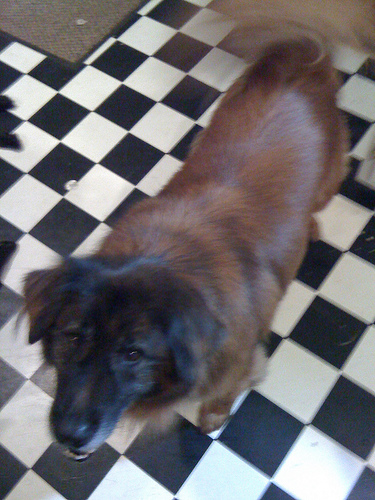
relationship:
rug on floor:
[0, 0, 151, 70] [0, 0, 371, 499]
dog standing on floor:
[24, 0, 375, 470] [0, 0, 371, 499]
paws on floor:
[0, 102, 19, 151] [0, 0, 371, 499]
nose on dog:
[53, 398, 105, 448] [24, 0, 375, 470]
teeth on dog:
[60, 446, 87, 459] [24, 0, 375, 470]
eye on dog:
[123, 344, 146, 366] [24, 0, 375, 470]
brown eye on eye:
[60, 328, 87, 347] [123, 344, 146, 366]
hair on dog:
[41, 44, 358, 466] [145, 67, 338, 310]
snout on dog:
[56, 405, 95, 447] [24, 0, 375, 470]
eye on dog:
[123, 344, 142, 365] [24, 0, 375, 470]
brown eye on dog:
[60, 328, 88, 351] [24, 0, 375, 470]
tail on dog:
[192, 0, 374, 67] [24, 0, 375, 470]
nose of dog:
[53, 408, 105, 447] [24, 0, 375, 470]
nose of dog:
[53, 398, 105, 448] [24, 0, 375, 470]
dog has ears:
[24, 0, 375, 470] [24, 255, 227, 384]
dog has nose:
[21, 77, 367, 470] [50, 410, 101, 448]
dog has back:
[24, 0, 375, 470] [112, 69, 330, 297]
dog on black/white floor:
[24, 0, 375, 470] [0, 0, 374, 499]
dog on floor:
[24, 0, 375, 470] [0, 0, 371, 499]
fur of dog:
[131, 144, 317, 312] [24, 0, 375, 470]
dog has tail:
[24, 0, 375, 470] [221, 0, 359, 54]